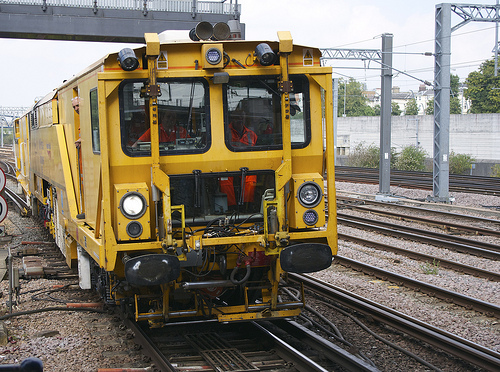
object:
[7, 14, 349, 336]
train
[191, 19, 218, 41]
horn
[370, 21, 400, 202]
poles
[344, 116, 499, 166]
wall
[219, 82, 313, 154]
window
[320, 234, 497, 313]
gravel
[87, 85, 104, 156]
window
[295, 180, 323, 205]
light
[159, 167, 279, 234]
window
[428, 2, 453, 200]
post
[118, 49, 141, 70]
headlight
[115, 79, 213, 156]
window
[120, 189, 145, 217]
light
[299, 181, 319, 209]
light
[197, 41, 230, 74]
light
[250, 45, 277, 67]
light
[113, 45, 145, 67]
light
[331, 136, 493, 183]
yard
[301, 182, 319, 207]
headlight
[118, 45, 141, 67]
spot lights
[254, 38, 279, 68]
spotlight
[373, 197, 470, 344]
tracks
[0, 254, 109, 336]
wire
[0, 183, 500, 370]
ground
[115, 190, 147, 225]
headlight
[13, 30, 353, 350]
yellow train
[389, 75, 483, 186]
far right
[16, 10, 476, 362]
train yard